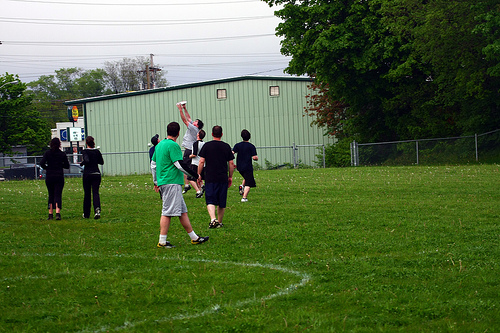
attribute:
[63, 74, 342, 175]
building — green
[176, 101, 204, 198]
man — jumping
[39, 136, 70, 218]
woman — talking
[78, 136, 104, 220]
woman — running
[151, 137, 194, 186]
shirt — green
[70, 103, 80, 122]
sign — yellow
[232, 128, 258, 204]
person — dressed, playing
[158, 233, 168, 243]
sock — white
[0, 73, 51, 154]
tree — growing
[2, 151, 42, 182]
vehicle — parked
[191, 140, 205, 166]
shirt — black, white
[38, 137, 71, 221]
person — standing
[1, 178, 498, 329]
grass — green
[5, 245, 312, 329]
circle — drawn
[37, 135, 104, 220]
two girls — hanging out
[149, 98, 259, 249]
boys — hanging out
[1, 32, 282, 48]
powerline — electric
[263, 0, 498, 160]
tree — big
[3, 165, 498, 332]
field — grassy